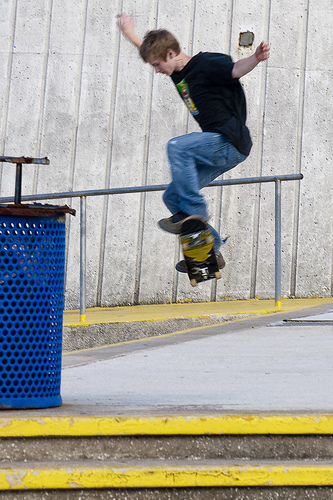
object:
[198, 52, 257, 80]
arm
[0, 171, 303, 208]
railing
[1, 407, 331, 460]
step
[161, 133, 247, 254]
jeans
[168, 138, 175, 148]
hole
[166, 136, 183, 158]
knee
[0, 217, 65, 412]
bin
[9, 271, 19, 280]
holes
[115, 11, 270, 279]
boy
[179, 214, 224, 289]
skateboard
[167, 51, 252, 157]
shirt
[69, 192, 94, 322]
railing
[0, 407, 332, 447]
line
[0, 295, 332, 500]
ground